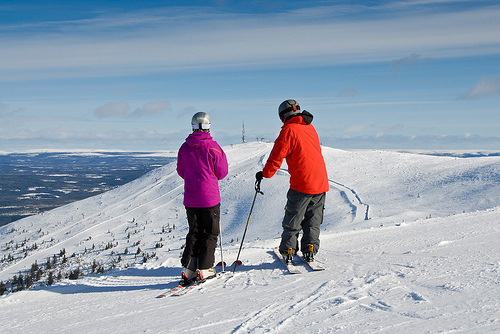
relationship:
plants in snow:
[31, 238, 89, 278] [7, 137, 499, 334]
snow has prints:
[7, 137, 499, 334] [247, 264, 439, 327]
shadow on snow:
[30, 281, 160, 298] [7, 137, 499, 334]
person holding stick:
[255, 93, 331, 273] [232, 174, 261, 266]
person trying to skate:
[255, 93, 331, 273] [269, 243, 323, 279]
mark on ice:
[334, 177, 378, 226] [7, 137, 499, 334]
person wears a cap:
[172, 106, 232, 284] [190, 106, 214, 134]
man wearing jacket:
[255, 93, 331, 273] [259, 117, 336, 200]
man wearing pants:
[255, 93, 331, 273] [274, 194, 326, 263]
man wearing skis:
[255, 93, 331, 273] [269, 243, 323, 279]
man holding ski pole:
[255, 93, 331, 273] [232, 174, 261, 266]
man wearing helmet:
[255, 93, 331, 273] [276, 97, 304, 123]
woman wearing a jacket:
[172, 106, 232, 284] [174, 130, 229, 208]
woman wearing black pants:
[172, 106, 232, 284] [181, 206, 221, 268]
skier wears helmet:
[255, 93, 331, 273] [276, 97, 304, 123]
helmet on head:
[276, 97, 304, 123] [276, 93, 313, 126]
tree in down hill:
[44, 255, 52, 271] [5, 193, 183, 315]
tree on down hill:
[60, 247, 66, 255] [5, 193, 183, 315]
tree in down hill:
[16, 274, 29, 292] [5, 193, 183, 315]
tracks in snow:
[334, 177, 378, 226] [7, 137, 499, 334]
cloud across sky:
[6, 7, 496, 76] [3, 2, 498, 139]